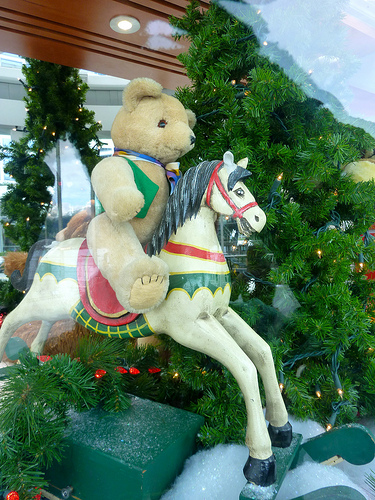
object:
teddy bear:
[85, 74, 198, 314]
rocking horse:
[1, 151, 294, 490]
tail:
[8, 238, 46, 293]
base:
[238, 422, 374, 499]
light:
[94, 369, 106, 378]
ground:
[329, 72, 358, 113]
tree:
[229, 82, 374, 352]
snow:
[162, 406, 362, 498]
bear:
[86, 75, 202, 318]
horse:
[0, 151, 295, 489]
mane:
[146, 159, 224, 259]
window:
[1, 51, 125, 254]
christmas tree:
[0, 1, 372, 490]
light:
[279, 382, 284, 390]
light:
[277, 172, 284, 182]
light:
[316, 249, 323, 257]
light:
[358, 262, 363, 273]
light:
[244, 90, 252, 96]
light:
[232, 79, 236, 85]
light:
[114, 366, 128, 374]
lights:
[319, 137, 323, 141]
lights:
[231, 79, 236, 85]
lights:
[337, 388, 344, 398]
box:
[45, 392, 207, 498]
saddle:
[77, 236, 162, 344]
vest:
[94, 148, 182, 221]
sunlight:
[93, 77, 110, 117]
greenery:
[220, 71, 361, 186]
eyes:
[157, 119, 167, 129]